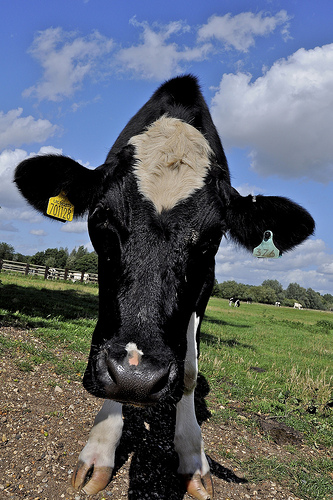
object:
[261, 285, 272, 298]
leaves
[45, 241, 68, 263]
leaves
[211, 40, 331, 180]
cloud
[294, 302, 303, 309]
white cow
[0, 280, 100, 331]
shade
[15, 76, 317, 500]
cow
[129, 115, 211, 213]
spot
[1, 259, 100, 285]
fence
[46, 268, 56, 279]
cow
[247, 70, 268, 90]
part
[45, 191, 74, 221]
tag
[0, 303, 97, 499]
dirt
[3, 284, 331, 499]
hills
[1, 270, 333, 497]
grass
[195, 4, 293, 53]
clouds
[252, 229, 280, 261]
blue tag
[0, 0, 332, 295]
sky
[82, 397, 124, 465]
leg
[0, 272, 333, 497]
ground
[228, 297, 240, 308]
cow grazing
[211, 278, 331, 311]
tree line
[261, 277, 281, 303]
tree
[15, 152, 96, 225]
cow's ear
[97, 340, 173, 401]
nose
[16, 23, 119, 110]
cloud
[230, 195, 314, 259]
ear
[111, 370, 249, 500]
shade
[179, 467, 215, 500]
hoof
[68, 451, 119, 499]
hoof